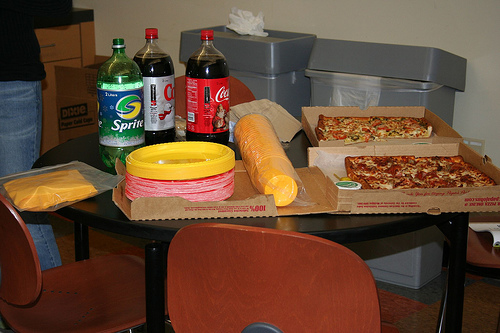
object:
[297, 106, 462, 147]
box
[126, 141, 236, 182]
lid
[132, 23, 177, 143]
bottle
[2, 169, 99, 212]
napkins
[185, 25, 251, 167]
coke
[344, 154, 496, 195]
pizza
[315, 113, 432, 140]
pizza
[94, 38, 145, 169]
bottles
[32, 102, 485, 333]
table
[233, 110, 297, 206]
water glass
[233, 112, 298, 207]
cups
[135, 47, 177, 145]
soda bottle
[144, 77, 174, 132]
gray label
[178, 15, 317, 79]
garbage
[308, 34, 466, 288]
plastic boxes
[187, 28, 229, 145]
bottle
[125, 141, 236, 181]
plate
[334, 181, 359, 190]
butter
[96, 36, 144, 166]
two liter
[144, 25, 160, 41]
lid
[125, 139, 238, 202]
plates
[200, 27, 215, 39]
cap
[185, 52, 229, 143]
soda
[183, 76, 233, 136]
red label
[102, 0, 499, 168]
wall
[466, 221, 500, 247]
paper towel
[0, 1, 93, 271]
person